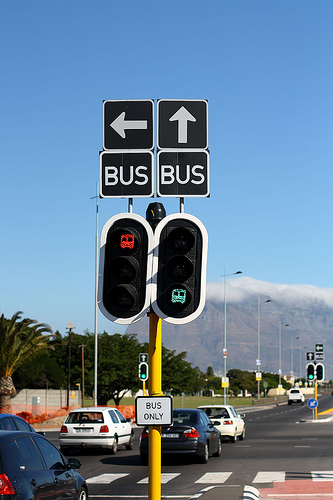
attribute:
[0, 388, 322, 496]
vehicles — back of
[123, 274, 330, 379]
mountain — hazy, distant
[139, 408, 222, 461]
car — is blue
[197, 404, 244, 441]
car — is white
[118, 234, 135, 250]
signal — red 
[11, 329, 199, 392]
tree — large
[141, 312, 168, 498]
post — metal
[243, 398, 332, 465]
road — black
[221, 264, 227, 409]
post — metal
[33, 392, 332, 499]
road — black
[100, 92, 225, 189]
sign — black, white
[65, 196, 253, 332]
sign — yellow, white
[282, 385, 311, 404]
white jeep — is white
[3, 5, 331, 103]
sky — clear, blue, daytime